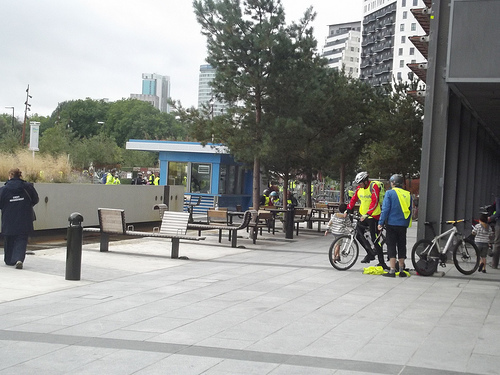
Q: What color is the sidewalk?
A: The sidewalk is grey.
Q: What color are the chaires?
A: The chaires are black and brown.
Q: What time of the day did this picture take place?
A: It took place in the day time.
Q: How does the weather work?
A: The weather looks cloudy.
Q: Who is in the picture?
A: Multiple people are in the picture.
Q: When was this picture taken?
A: It was taken in the day time.